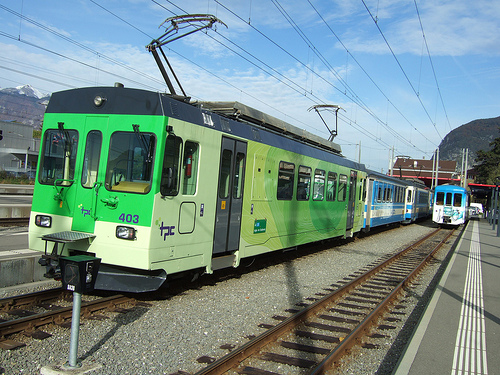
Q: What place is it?
A: It is a train station.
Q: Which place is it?
A: It is a train station.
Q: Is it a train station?
A: Yes, it is a train station.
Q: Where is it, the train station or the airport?
A: It is the train station.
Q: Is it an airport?
A: No, it is a train station.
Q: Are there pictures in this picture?
A: No, there are no pictures.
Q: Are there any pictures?
A: No, there are no pictures.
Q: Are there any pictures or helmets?
A: No, there are no pictures or helmets.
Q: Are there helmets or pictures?
A: No, there are no pictures or helmets.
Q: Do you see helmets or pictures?
A: No, there are no pictures or helmets.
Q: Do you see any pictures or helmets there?
A: No, there are no pictures or helmets.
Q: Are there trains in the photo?
A: Yes, there is a train.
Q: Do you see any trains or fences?
A: Yes, there is a train.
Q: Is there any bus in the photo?
A: No, there are no buses.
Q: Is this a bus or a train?
A: This is a train.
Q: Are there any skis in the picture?
A: No, there are no skis.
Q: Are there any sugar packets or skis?
A: No, there are no skis or sugar packets.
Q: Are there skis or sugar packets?
A: No, there are no skis or sugar packets.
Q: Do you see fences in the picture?
A: No, there are no fences.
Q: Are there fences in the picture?
A: No, there are no fences.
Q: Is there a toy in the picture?
A: No, there are no toys.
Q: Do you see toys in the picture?
A: No, there are no toys.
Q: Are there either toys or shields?
A: No, there are no toys or shields.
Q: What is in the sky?
A: The clouds are in the sky.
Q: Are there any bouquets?
A: No, there are no bouquets.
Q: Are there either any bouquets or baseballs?
A: No, there are no bouquets or baseballs.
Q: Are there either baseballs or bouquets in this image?
A: No, there are no bouquets or baseballs.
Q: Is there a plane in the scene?
A: No, there are no airplanes.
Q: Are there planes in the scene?
A: No, there are no planes.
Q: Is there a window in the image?
A: Yes, there are windows.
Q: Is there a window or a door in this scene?
A: Yes, there are windows.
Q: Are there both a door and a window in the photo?
A: Yes, there are both a window and a door.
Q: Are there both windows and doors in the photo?
A: Yes, there are both windows and a door.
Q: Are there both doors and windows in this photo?
A: Yes, there are both windows and a door.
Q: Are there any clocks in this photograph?
A: No, there are no clocks.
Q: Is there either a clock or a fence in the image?
A: No, there are no clocks or fences.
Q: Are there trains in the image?
A: Yes, there is a train.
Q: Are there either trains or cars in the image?
A: Yes, there is a train.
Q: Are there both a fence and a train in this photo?
A: No, there is a train but no fences.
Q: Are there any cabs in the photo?
A: No, there are no cabs.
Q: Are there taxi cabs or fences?
A: No, there are no taxi cabs or fences.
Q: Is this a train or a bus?
A: This is a train.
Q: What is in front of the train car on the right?
A: The train is in front of the train car.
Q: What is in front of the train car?
A: The train is in front of the train car.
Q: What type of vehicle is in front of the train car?
A: The vehicle is a train.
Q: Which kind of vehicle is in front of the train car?
A: The vehicle is a train.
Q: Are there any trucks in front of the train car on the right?
A: No, there is a train in front of the train car.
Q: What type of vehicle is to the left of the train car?
A: The vehicle is a train.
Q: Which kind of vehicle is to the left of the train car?
A: The vehicle is a train.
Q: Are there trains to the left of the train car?
A: Yes, there is a train to the left of the train car.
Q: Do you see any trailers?
A: No, there are no trailers.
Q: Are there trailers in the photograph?
A: No, there are no trailers.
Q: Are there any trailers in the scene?
A: No, there are no trailers.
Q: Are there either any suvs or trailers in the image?
A: No, there are no trailers or suvs.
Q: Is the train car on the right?
A: Yes, the train car is on the right of the image.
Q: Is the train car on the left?
A: No, the train car is on the right of the image.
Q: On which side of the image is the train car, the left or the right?
A: The train car is on the right of the image.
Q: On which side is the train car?
A: The train car is on the right of the image.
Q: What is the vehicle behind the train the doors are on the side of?
A: The vehicle is a train car.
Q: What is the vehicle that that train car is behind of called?
A: The vehicle is a train.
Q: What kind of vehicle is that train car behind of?
A: The train car is behind the train.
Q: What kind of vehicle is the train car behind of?
A: The train car is behind the train.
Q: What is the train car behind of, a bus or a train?
A: The train car is behind a train.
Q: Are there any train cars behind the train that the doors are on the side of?
A: Yes, there is a train car behind the train.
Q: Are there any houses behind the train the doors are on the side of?
A: No, there is a train car behind the train.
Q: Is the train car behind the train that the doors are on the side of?
A: Yes, the train car is behind the train.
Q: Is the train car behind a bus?
A: No, the train car is behind the train.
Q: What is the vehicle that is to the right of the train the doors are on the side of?
A: The vehicle is a train car.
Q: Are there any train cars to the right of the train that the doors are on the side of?
A: Yes, there is a train car to the right of the train.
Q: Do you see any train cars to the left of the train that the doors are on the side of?
A: No, the train car is to the right of the train.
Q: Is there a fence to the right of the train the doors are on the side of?
A: No, there is a train car to the right of the train.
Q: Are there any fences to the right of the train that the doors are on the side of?
A: No, there is a train car to the right of the train.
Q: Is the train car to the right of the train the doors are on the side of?
A: Yes, the train car is to the right of the train.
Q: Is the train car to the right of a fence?
A: No, the train car is to the right of the train.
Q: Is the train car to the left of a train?
A: No, the train car is to the right of a train.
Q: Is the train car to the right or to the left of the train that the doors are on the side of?
A: The train car is to the right of the train.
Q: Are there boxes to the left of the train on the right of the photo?
A: No, there is a train car to the left of the train.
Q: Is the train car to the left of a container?
A: No, the train car is to the left of a train.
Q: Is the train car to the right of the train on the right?
A: No, the train car is to the left of the train.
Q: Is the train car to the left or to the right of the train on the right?
A: The train car is to the left of the train.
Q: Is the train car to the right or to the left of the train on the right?
A: The train car is to the left of the train.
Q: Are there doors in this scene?
A: Yes, there are doors.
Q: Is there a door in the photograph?
A: Yes, there are doors.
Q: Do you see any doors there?
A: Yes, there are doors.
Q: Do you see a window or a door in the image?
A: Yes, there are doors.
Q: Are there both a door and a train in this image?
A: Yes, there are both a door and a train.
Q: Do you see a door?
A: Yes, there are doors.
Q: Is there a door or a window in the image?
A: Yes, there are doors.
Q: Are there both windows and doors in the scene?
A: Yes, there are both doors and a window.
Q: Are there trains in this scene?
A: Yes, there is a train.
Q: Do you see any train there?
A: Yes, there is a train.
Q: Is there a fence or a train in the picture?
A: Yes, there is a train.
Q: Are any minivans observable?
A: No, there are no minivans.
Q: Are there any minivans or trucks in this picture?
A: No, there are no minivans or trucks.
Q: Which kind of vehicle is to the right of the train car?
A: The vehicle is a train.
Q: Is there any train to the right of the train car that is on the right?
A: Yes, there is a train to the right of the train car.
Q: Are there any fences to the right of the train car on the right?
A: No, there is a train to the right of the train car.